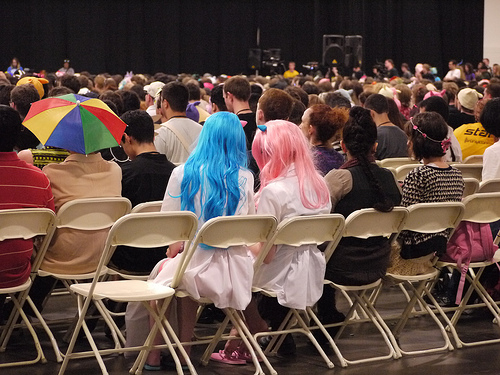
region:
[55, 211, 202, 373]
a light colored folding chair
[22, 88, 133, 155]
a multicolored umbrella hat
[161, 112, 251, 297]
a person with blue hair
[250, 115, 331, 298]
a person with pink hair and blue horns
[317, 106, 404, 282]
a person wearing a black vest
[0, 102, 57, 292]
a person wearing a red striped shirt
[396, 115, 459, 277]
a person with dark colored hair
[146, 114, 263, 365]
a woman wearing a white dress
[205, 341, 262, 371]
pink sandals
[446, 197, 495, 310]
a pink back pack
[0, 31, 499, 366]
Auditorium is full of people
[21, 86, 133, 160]
Umbrella is multicolored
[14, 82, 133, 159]
Umbrella is yellow, blue, red and green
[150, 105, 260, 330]
Woman with blue wig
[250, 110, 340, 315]
Woman with pink wig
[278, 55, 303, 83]
Person wears yellow shirt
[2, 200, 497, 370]
Chairs are color ivory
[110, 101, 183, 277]
Man wears black shirt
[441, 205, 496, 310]
Backpack is pink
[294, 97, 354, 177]
Woman is old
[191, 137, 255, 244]
Person has blue hair.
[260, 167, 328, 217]
Person has pink hair.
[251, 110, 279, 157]
Person has blue horn.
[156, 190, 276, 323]
Person is wearing white shirt.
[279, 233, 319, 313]
Person is wearing white shirt.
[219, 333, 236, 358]
Person wearing pink shoes.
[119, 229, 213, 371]
People sitting in white folding chairs.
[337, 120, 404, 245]
Person has long dark hair.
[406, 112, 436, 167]
Person has band around head.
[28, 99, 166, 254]
Person has umbrella hat on head.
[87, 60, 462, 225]
crowd of people seated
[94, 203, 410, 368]
white folding chairs on floor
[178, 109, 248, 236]
long blue hair on girl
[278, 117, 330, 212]
pink hair on girl's back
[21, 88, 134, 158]
colored umbrella on head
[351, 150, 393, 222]
long braid on back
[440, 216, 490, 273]
pink bag on chair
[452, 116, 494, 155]
yellow shirt with words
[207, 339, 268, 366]
pink sandles on floor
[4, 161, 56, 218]
red shirt with stripes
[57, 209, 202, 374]
An empty chair in an auditorium.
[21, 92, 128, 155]
A multicolored umbrella.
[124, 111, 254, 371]
A girl with blue hair.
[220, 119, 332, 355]
A girl with pink hair.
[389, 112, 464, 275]
A girl sitting in an auditorium.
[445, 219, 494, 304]
A pink backpack.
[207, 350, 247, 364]
A pink flip flop.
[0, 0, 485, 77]
A black curtain.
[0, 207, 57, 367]
An occupied chair.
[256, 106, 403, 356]
A woman sitting in a chair.